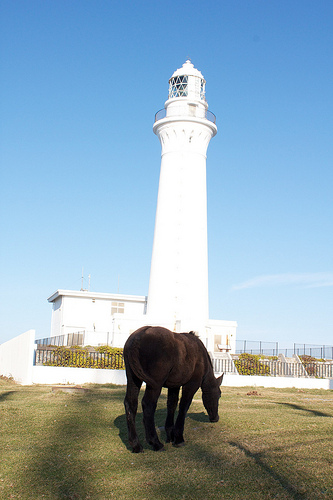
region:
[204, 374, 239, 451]
The horse has a rather large face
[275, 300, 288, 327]
There is a light blue sky that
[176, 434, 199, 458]
This horse has very large hooves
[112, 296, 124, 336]
There is a large window in this home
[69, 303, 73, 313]
This home has a bright white color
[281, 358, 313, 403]
There is a stairwell that is pictured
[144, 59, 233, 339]
This is a light tower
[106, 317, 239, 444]
This is a horse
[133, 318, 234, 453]
The horse is bent over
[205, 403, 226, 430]
The horse is eating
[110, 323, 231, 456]
The horse is standing still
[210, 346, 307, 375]
Two small flights of stairs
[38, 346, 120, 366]
A short fence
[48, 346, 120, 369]
Vines are growing on the fence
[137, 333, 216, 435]
Only the right side of the horse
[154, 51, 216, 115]
large building window top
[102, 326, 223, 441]
a large brown horse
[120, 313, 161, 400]
horses tail is curled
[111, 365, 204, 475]
the horse has 4 legs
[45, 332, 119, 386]
green grown on fence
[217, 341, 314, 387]
a few white stairs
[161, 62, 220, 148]
a very large building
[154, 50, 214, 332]
white tower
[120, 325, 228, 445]
brown horse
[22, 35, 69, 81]
white clouds in blue sky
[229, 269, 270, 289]
white clouds in blue sky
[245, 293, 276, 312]
white clouds in blue sky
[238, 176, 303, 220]
white clouds in blue sky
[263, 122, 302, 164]
white clouds in blue sky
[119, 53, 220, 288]
a tall white lighthouse tower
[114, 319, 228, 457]
a horse grazes near the lighthouse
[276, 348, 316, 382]
steps lead up to the lighthouse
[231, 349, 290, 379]
ground shrubbery decorates the area in front of the lighthouse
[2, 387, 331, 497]
the grass here is very short and sparse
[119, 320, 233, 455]
the horse is black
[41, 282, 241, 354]
the living quarters of the lighthouse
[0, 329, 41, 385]
a high white wall on one side of the lighthouse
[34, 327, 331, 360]
a chain link fence around the lighthouse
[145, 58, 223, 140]
the lighthouse tower has an outdoor walkway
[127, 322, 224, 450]
the horse is black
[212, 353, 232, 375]
the stairs are white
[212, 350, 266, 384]
bush is beside the steps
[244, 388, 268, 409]
poop is in the grass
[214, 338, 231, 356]
plaque is in front of house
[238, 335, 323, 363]
the fence is black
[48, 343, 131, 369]
the bushes are yellow green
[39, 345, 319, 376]
bushes behind the fence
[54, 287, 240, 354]
the house is white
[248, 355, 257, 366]
green leaves on the bush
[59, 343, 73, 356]
green leaves on the bush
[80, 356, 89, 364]
green leaves on the bush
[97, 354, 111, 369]
green leaves on the bush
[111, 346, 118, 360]
green leaves on the bush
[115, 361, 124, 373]
green leaves on the bush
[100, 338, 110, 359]
green leaves on the bush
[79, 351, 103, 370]
green leaves on the bush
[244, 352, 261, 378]
green leaves on the bush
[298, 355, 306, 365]
green leaves on the bush